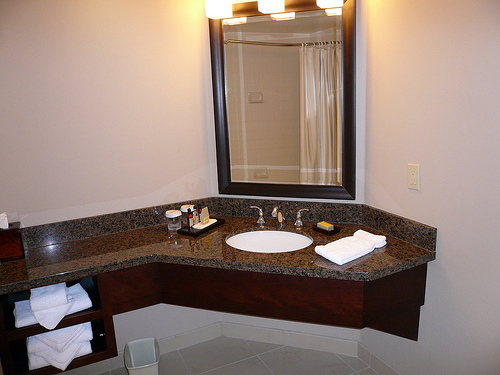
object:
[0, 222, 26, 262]
tissues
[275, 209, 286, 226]
faucet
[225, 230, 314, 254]
bowl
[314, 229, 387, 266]
towel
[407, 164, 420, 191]
outlet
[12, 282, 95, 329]
towels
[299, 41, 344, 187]
curtain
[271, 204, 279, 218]
water faucet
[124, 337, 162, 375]
garbage can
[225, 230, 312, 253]
sink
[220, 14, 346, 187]
mirror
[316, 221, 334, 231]
soap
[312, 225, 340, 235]
dish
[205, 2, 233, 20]
light fixture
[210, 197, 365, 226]
facets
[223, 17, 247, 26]
lights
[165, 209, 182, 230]
glass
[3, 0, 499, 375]
bathroom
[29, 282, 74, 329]
towels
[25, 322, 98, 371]
towels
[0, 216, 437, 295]
counter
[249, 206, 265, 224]
faucet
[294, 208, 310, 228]
faucet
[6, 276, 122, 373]
shelf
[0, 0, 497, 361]
wall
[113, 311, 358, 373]
baseboard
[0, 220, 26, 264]
box